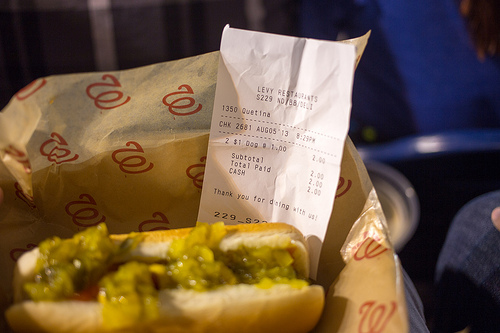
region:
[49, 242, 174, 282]
The relish is green.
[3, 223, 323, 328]
The hot dog bun is brown.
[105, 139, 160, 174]
The letter on the wrapper is red.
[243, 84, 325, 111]
The writing on the receipt is black.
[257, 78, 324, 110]
The writing is in English.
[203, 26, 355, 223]
The receipt is white and black.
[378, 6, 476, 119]
The man's shirt is blue.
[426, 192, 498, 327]
The man is wearing blue jeans.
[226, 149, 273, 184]
The writing on the receipt is in black.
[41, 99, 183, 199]
The food wrapper is red and brown.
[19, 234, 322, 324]
hot dog with lots of relish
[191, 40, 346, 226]
receipt for the food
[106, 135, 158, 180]
w on the brown paper under the hot dog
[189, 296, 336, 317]
hot dog bun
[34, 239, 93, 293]
green hot dog relish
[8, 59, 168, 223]
brown paper under the hotdog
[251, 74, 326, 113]
restaurant name and address on receipt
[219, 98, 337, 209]
order on the receipt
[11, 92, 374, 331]
hot dog and the receipt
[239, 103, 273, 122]
cashier's name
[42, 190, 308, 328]
a hot dog with pickle relish on it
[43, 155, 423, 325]
a hot dog sitting in a hot dog bun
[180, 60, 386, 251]
a receipt near a hot dog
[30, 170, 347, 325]
a hot dog near a receipt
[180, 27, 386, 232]
a receipt with the cost of the hot dog on it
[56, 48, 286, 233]
brown paper with a red w on it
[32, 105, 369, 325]
a hot dog sitting on brown paper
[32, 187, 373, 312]
lots of relish on a hot dog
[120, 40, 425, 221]
a receipt sitting on brown paper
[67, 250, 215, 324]
relish on a hot dog bun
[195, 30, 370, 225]
Dinner receipt for hot dogs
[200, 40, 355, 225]
Levy Restaurants dinner receipt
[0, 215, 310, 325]
Hot dog with relish on a bun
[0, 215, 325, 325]
Hotdog with condiments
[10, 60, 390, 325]
Paper liner with a W logo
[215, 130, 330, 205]
2 Hot dogs purchased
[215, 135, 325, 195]
Cash payment for hot dogs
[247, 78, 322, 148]
Levy Restaurant purchase at 8:22 p.m.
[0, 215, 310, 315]
Relish on a hot dog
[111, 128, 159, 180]
logo for restaurant chain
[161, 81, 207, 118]
the letter is red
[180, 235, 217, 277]
the relish is green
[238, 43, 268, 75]
the receipt is white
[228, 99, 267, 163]
the words are black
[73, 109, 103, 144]
the package is tan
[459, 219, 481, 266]
the pants are blue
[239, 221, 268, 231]
the outside of the bun is brown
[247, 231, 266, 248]
the inside of the bun is white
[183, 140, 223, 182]
the receipt is leaning on the paper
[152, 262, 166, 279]
the mustard is yellow